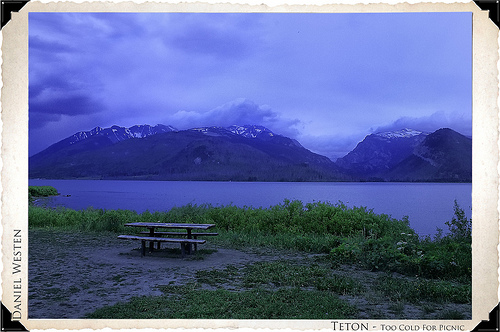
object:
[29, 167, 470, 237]
lake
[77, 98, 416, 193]
fluffy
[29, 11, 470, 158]
sky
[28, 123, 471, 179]
mountain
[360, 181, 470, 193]
ripple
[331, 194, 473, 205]
ripple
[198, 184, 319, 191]
ripple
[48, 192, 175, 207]
ripple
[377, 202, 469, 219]
ripple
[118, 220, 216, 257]
bench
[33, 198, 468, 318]
grass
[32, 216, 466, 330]
shore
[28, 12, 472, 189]
blue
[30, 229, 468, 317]
ground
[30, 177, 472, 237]
water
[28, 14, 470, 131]
cloud